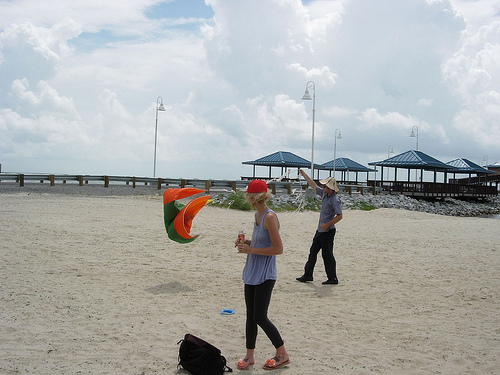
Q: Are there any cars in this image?
A: No, there are no cars.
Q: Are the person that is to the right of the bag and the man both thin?
A: Yes, both the person and the man are thin.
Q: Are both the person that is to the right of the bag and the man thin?
A: Yes, both the person and the man are thin.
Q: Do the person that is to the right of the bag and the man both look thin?
A: Yes, both the person and the man are thin.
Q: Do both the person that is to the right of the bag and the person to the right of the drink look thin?
A: Yes, both the person and the man are thin.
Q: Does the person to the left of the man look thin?
A: Yes, the person is thin.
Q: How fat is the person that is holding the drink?
A: The person is thin.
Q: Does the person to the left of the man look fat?
A: No, the person is thin.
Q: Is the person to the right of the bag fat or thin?
A: The person is thin.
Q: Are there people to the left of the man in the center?
A: Yes, there is a person to the left of the man.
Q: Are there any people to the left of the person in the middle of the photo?
A: Yes, there is a person to the left of the man.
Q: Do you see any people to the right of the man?
A: No, the person is to the left of the man.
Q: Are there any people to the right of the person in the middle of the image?
A: No, the person is to the left of the man.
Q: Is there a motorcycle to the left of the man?
A: No, there is a person to the left of the man.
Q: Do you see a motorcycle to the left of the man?
A: No, there is a person to the left of the man.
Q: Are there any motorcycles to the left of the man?
A: No, there is a person to the left of the man.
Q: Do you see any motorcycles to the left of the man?
A: No, there is a person to the left of the man.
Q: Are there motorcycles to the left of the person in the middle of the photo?
A: No, there is a person to the left of the man.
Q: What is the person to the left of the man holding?
A: The person is holding the drink.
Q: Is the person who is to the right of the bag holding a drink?
A: Yes, the person is holding a drink.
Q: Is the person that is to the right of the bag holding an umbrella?
A: No, the person is holding a drink.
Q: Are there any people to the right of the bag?
A: Yes, there is a person to the right of the bag.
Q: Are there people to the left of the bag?
A: No, the person is to the right of the bag.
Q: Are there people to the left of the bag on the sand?
A: No, the person is to the right of the bag.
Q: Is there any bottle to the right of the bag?
A: No, there is a person to the right of the bag.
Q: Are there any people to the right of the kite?
A: Yes, there is a person to the right of the kite.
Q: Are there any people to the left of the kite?
A: No, the person is to the right of the kite.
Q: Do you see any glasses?
A: No, there are no glasses.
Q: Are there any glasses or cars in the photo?
A: No, there are no glasses or cars.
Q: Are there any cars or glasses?
A: No, there are no glasses or cars.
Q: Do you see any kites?
A: Yes, there is a kite.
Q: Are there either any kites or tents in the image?
A: Yes, there is a kite.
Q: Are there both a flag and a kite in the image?
A: No, there is a kite but no flags.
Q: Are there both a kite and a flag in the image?
A: No, there is a kite but no flags.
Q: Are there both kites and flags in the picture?
A: No, there is a kite but no flags.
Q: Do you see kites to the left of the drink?
A: Yes, there is a kite to the left of the drink.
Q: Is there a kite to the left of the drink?
A: Yes, there is a kite to the left of the drink.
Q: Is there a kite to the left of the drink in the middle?
A: Yes, there is a kite to the left of the drink.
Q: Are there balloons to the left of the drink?
A: No, there is a kite to the left of the drink.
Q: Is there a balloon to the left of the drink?
A: No, there is a kite to the left of the drink.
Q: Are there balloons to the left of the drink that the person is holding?
A: No, there is a kite to the left of the drink.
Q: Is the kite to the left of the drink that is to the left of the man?
A: Yes, the kite is to the left of the drink.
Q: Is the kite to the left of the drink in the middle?
A: Yes, the kite is to the left of the drink.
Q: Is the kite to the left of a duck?
A: No, the kite is to the left of the drink.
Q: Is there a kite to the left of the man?
A: Yes, there is a kite to the left of the man.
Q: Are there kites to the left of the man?
A: Yes, there is a kite to the left of the man.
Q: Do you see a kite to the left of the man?
A: Yes, there is a kite to the left of the man.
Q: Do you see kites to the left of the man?
A: Yes, there is a kite to the left of the man.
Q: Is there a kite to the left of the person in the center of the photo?
A: Yes, there is a kite to the left of the man.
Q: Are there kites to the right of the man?
A: No, the kite is to the left of the man.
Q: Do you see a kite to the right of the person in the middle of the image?
A: No, the kite is to the left of the man.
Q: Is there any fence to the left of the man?
A: No, there is a kite to the left of the man.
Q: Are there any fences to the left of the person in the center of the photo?
A: No, there is a kite to the left of the man.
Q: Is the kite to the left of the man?
A: Yes, the kite is to the left of the man.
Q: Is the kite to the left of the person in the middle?
A: Yes, the kite is to the left of the man.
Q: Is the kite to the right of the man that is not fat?
A: No, the kite is to the left of the man.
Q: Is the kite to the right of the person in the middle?
A: No, the kite is to the left of the man.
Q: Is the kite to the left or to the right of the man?
A: The kite is to the left of the man.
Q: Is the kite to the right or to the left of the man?
A: The kite is to the left of the man.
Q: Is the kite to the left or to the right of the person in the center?
A: The kite is to the left of the man.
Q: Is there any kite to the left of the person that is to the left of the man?
A: Yes, there is a kite to the left of the person.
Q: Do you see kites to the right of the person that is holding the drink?
A: No, the kite is to the left of the person.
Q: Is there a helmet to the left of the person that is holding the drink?
A: No, there is a kite to the left of the person.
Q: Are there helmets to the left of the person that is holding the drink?
A: No, there is a kite to the left of the person.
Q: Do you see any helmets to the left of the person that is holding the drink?
A: No, there is a kite to the left of the person.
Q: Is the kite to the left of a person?
A: Yes, the kite is to the left of a person.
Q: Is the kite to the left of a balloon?
A: No, the kite is to the left of a person.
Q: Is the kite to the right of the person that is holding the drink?
A: No, the kite is to the left of the person.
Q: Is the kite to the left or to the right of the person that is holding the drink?
A: The kite is to the left of the person.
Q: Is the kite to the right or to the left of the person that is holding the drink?
A: The kite is to the left of the person.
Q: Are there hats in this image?
A: Yes, there is a hat.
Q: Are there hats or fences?
A: Yes, there is a hat.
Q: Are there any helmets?
A: No, there are no helmets.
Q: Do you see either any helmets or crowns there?
A: No, there are no helmets or crowns.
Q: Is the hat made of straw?
A: Yes, the hat is made of straw.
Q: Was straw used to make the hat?
A: Yes, the hat is made of straw.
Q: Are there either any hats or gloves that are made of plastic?
A: No, there is a hat but it is made of straw.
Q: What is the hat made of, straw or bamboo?
A: The hat is made of straw.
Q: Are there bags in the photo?
A: Yes, there is a bag.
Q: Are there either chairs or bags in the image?
A: Yes, there is a bag.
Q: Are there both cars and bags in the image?
A: No, there is a bag but no cars.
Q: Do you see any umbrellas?
A: No, there are no umbrellas.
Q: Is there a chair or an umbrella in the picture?
A: No, there are no umbrellas or chairs.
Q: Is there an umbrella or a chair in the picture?
A: No, there are no umbrellas or chairs.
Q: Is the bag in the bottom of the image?
A: Yes, the bag is in the bottom of the image.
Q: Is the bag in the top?
A: No, the bag is in the bottom of the image.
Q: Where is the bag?
A: The bag is on the sand.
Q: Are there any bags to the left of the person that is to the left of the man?
A: Yes, there is a bag to the left of the person.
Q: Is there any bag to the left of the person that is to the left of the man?
A: Yes, there is a bag to the left of the person.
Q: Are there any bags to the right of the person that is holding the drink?
A: No, the bag is to the left of the person.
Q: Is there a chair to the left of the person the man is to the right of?
A: No, there is a bag to the left of the person.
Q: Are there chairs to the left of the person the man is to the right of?
A: No, there is a bag to the left of the person.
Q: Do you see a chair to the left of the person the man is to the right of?
A: No, there is a bag to the left of the person.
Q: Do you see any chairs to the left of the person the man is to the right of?
A: No, there is a bag to the left of the person.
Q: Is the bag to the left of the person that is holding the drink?
A: Yes, the bag is to the left of the person.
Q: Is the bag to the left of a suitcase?
A: No, the bag is to the left of the person.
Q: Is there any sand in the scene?
A: Yes, there is sand.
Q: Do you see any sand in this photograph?
A: Yes, there is sand.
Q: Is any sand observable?
A: Yes, there is sand.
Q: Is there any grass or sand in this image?
A: Yes, there is sand.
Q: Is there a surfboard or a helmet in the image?
A: No, there are no helmets or surfboards.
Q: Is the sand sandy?
A: Yes, the sand is sandy.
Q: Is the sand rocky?
A: No, the sand is sandy.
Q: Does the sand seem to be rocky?
A: No, the sand is sandy.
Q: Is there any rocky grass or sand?
A: No, there is sand but it is sandy.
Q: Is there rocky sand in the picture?
A: No, there is sand but it is sandy.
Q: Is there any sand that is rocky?
A: No, there is sand but it is sandy.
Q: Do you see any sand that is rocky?
A: No, there is sand but it is sandy.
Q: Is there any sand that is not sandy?
A: No, there is sand but it is sandy.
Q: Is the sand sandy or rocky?
A: The sand is sandy.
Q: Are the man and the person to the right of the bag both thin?
A: Yes, both the man and the person are thin.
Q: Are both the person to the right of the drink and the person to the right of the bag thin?
A: Yes, both the man and the person are thin.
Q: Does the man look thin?
A: Yes, the man is thin.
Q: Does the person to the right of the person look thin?
A: Yes, the man is thin.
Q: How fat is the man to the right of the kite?
A: The man is thin.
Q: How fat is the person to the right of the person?
A: The man is thin.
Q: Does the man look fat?
A: No, the man is thin.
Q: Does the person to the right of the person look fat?
A: No, the man is thin.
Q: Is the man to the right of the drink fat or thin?
A: The man is thin.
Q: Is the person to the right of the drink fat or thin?
A: The man is thin.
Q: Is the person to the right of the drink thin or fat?
A: The man is thin.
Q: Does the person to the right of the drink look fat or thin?
A: The man is thin.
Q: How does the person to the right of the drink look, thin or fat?
A: The man is thin.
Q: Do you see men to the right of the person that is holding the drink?
A: Yes, there is a man to the right of the person.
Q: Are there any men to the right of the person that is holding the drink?
A: Yes, there is a man to the right of the person.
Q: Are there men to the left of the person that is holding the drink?
A: No, the man is to the right of the person.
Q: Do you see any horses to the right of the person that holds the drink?
A: No, there is a man to the right of the person.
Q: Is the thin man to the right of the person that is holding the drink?
A: Yes, the man is to the right of the person.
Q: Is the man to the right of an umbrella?
A: No, the man is to the right of the person.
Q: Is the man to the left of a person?
A: No, the man is to the right of a person.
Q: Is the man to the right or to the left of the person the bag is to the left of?
A: The man is to the right of the person.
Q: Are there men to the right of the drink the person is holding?
A: Yes, there is a man to the right of the drink.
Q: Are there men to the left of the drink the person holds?
A: No, the man is to the right of the drink.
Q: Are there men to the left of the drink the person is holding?
A: No, the man is to the right of the drink.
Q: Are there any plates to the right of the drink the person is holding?
A: No, there is a man to the right of the drink.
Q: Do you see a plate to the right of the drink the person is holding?
A: No, there is a man to the right of the drink.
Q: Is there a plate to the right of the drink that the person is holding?
A: No, there is a man to the right of the drink.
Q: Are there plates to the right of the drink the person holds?
A: No, there is a man to the right of the drink.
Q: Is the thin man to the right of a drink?
A: Yes, the man is to the right of a drink.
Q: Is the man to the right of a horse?
A: No, the man is to the right of a drink.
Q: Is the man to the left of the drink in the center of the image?
A: No, the man is to the right of the drink.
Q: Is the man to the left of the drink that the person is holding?
A: No, the man is to the right of the drink.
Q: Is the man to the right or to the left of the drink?
A: The man is to the right of the drink.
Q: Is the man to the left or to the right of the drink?
A: The man is to the right of the drink.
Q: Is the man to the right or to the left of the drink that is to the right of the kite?
A: The man is to the right of the drink.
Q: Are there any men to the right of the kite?
A: Yes, there is a man to the right of the kite.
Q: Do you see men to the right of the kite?
A: Yes, there is a man to the right of the kite.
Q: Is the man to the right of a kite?
A: Yes, the man is to the right of a kite.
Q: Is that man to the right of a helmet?
A: No, the man is to the right of a kite.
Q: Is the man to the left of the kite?
A: No, the man is to the right of the kite.